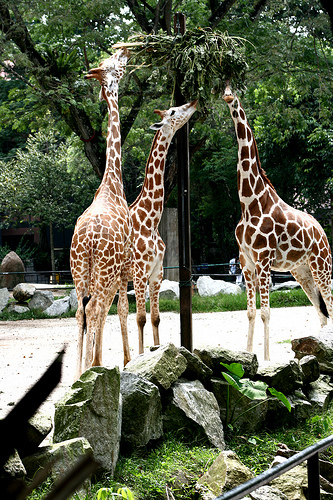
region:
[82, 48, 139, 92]
head of a giraffe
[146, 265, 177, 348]
leg of a giraffe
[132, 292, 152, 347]
leg of a giraffe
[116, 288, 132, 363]
leg of a giraffe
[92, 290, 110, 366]
leg of a giraffe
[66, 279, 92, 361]
leg of a giraffe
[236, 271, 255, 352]
leg of a giraffe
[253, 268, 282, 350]
leg of a giraffe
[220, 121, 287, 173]
neck of a giraffe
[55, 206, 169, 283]
body of a giraffe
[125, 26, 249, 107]
green leaves in a feeder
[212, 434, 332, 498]
a metal hand rail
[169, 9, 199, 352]
a black pole holding a feeder for giraffes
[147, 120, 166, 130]
the ear of a giraffe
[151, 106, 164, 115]
a brown horn on a giraffe's head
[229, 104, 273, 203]
a long neck on a giraffe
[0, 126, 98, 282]
a tree next to a giraffe pen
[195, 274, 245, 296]
a large rock in a giraffe pen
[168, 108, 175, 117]
the eye of a giraffe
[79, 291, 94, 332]
black hair at the end of a giraffe's tail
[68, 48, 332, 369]
three giraffes gather to eat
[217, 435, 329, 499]
a metal railing in the foreground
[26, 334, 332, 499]
large rocks cover the area below a pole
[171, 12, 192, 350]
a tall black pole is for feeding giraffes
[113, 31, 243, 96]
greens mounted high on pole for giraffes to eat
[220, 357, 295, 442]
a large green leafed weed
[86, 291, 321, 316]
tall green grass on the ground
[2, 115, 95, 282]
a slender trunked young tree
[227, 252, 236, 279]
a oerson in a white shirt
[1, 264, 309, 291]
a fence across far side of the zoo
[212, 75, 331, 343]
A tall brown and white giraffe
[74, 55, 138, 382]
A tall brown and white giraffe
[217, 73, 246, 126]
A tall brown and white giraffe's head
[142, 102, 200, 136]
A tall brown and white giraffe's head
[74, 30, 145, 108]
A tall brown and white giraffe's head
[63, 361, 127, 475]
A big grey stone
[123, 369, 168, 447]
A big grey stone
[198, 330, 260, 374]
A big grey stone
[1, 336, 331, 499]
these are large rocks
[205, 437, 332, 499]
this is a black rail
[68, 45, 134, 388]
this is a giraffe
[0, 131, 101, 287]
thats a green tree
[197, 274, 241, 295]
thats a white rock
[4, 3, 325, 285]
these are the trees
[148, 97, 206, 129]
this is the giraffe head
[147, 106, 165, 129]
those are his ears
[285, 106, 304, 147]
green leaves on the tree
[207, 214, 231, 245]
green leaves on the tree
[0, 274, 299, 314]
The rocks in the background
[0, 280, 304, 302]
A set of rocks in the background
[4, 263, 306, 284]
A black metal fence in the background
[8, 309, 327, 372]
The concrete area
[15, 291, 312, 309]
The grass in front the rocks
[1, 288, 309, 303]
A set of grass in front the rocks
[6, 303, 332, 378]
The concrete area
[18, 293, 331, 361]
A concrete area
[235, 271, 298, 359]
The front feet of the giraffe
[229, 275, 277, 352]
A set of front feet on the giraffe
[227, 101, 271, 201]
the neck is long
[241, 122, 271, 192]
the neck has a mane